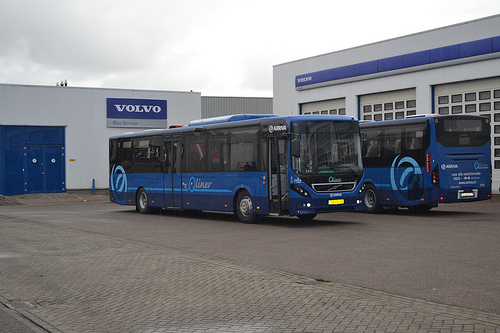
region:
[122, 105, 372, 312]
a bus on teh road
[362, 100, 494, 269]
a bus on the road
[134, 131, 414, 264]
a blue passenger bus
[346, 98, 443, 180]
a blue passenger bus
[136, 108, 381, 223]
a large blue bus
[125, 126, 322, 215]
a large passenger bus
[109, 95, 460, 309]
a bus on the road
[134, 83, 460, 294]
a blue bus on the road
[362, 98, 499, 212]
a blue bus on the road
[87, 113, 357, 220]
a passenger bus on the road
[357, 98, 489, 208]
a passenger bus on the road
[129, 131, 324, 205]
a blue passenger bus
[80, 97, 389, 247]
a blue passenger bus on the raod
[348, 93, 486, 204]
a blue passenger bus on the raod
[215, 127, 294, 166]
window on bus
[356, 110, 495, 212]
a large blue bus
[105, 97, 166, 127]
a large VOLVO sign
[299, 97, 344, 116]
a large garage door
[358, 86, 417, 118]
a large garage door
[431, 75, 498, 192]
a large garage door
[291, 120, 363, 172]
a bus front windshield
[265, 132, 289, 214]
a bus entry door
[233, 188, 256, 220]
a bus front tire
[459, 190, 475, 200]
a bus license plate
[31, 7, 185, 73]
Clouds in the sky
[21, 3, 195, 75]
Dark clouds in the sky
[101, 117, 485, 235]
Two buses side by side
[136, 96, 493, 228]
Two blue buses side by side